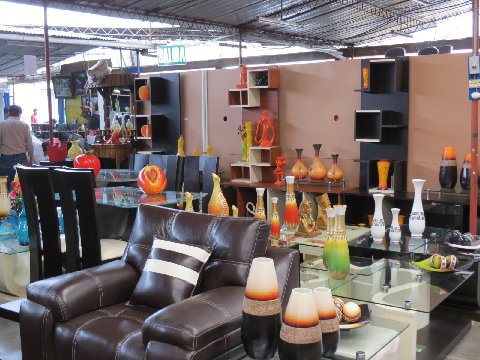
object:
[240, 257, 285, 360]
candle holder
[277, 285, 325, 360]
candle holder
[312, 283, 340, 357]
candle holder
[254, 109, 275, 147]
orange object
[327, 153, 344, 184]
vase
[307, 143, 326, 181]
vase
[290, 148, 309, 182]
vase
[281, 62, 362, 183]
wall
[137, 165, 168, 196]
flower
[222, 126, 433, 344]
objects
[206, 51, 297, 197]
shelf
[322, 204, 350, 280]
vase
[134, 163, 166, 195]
sculpture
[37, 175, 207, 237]
table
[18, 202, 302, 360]
chair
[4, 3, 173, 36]
light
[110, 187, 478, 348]
table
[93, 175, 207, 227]
table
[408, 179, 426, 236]
vase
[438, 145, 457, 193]
vase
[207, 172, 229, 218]
vase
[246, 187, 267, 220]
vase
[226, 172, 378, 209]
table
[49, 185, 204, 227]
table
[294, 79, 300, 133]
ground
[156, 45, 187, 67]
sign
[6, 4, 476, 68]
rafters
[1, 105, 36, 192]
man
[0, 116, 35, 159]
shirt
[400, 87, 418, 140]
wall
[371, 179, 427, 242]
vases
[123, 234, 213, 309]
pillow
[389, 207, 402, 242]
vase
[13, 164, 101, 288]
chair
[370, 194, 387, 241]
vase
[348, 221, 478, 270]
table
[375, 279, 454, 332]
base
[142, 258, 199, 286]
line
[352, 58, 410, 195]
door